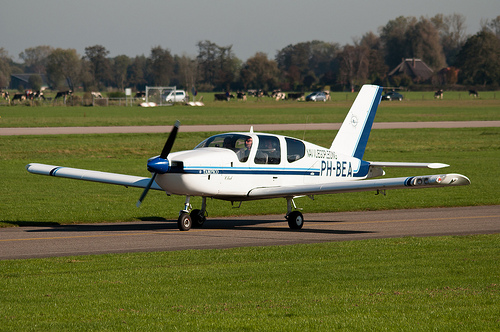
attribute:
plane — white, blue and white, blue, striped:
[26, 79, 469, 230]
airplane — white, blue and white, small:
[30, 83, 470, 231]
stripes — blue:
[181, 166, 357, 178]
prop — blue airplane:
[136, 123, 180, 203]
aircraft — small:
[21, 81, 472, 233]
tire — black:
[286, 208, 306, 230]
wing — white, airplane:
[230, 170, 470, 200]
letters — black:
[318, 158, 353, 178]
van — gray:
[165, 86, 190, 104]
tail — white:
[328, 82, 384, 158]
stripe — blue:
[356, 85, 378, 155]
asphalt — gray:
[37, 223, 166, 252]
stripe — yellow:
[3, 230, 88, 242]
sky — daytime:
[0, 1, 478, 84]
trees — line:
[5, 40, 354, 92]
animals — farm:
[14, 81, 291, 107]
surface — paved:
[67, 222, 137, 252]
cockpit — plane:
[202, 132, 280, 167]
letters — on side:
[303, 145, 376, 192]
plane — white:
[86, 76, 481, 256]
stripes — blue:
[191, 148, 311, 184]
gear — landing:
[131, 179, 341, 244]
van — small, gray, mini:
[162, 88, 188, 102]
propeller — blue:
[139, 122, 182, 202]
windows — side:
[253, 134, 311, 166]